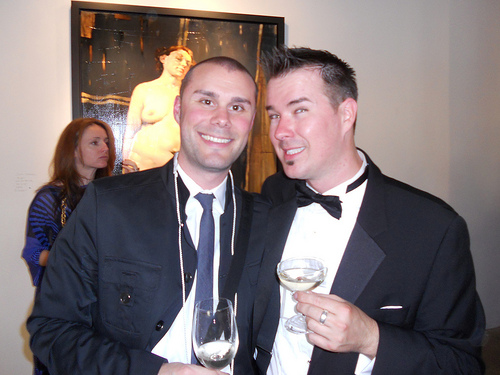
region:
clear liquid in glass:
[265, 271, 333, 290]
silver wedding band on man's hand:
[315, 306, 354, 323]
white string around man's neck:
[175, 183, 202, 270]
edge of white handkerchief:
[373, 296, 404, 314]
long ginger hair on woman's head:
[53, 111, 121, 203]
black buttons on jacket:
[109, 276, 149, 323]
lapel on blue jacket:
[337, 220, 388, 298]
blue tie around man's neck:
[172, 181, 235, 343]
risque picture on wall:
[60, 4, 183, 119]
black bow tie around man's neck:
[283, 186, 383, 236]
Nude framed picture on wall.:
[82, 352, 85, 373]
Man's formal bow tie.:
[295, 175, 391, 226]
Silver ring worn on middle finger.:
[315, 306, 330, 326]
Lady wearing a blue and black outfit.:
[25, 117, 100, 272]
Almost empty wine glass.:
[190, 290, 240, 372]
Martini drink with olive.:
[274, 248, 334, 335]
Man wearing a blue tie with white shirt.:
[176, 65, 242, 308]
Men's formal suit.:
[255, 166, 466, 371]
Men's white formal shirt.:
[260, 50, 375, 245]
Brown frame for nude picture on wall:
[2, 0, 289, 85]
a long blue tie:
[195, 191, 230, 308]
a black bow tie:
[290, 173, 360, 220]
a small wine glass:
[261, 259, 327, 342]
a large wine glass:
[192, 294, 247, 373]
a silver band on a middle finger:
[310, 302, 335, 334]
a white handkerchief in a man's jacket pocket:
[378, 301, 407, 316]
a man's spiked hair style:
[255, 41, 353, 98]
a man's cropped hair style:
[190, 59, 266, 96]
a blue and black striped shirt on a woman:
[27, 193, 70, 248]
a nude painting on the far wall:
[75, 11, 176, 134]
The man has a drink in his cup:
[175, 287, 264, 372]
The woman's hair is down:
[37, 100, 142, 200]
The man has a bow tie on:
[276, 170, 411, 237]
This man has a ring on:
[297, 295, 364, 340]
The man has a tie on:
[182, 172, 231, 366]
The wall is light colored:
[10, 94, 65, 176]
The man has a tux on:
[256, 97, 496, 352]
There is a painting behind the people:
[70, 2, 345, 202]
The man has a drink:
[263, 250, 364, 355]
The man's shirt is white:
[276, 210, 443, 331]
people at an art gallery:
[17, 10, 493, 373]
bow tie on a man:
[290, 183, 358, 220]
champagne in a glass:
[274, 253, 333, 338]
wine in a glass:
[182, 292, 249, 366]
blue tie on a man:
[188, 188, 223, 302]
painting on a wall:
[64, 1, 204, 69]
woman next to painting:
[11, 111, 141, 298]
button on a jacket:
[143, 314, 170, 336]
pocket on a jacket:
[97, 247, 167, 340]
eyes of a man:
[194, 90, 253, 117]